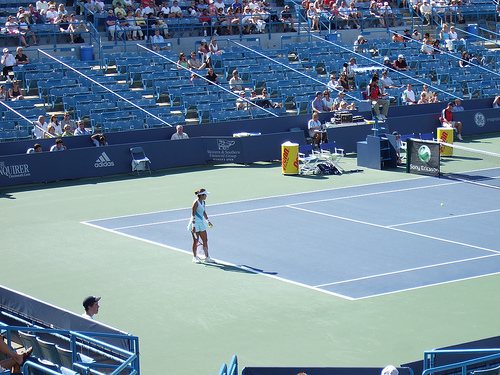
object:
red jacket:
[366, 83, 380, 99]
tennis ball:
[209, 225, 213, 229]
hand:
[208, 222, 212, 226]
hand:
[192, 227, 197, 234]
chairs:
[298, 147, 345, 176]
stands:
[0, 0, 500, 144]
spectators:
[392, 23, 465, 55]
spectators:
[32, 112, 92, 139]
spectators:
[177, 38, 226, 70]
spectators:
[299, 0, 460, 28]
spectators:
[0, 0, 80, 48]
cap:
[197, 189, 211, 195]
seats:
[11, 48, 289, 134]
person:
[229, 70, 245, 92]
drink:
[281, 141, 299, 175]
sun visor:
[205, 191, 211, 195]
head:
[195, 188, 208, 199]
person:
[171, 125, 189, 140]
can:
[281, 141, 299, 176]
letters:
[282, 148, 290, 170]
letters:
[293, 148, 299, 171]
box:
[187, 189, 214, 263]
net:
[406, 138, 500, 189]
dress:
[187, 221, 207, 232]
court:
[0, 0, 500, 375]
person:
[308, 113, 328, 147]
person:
[338, 72, 354, 92]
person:
[441, 102, 464, 140]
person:
[229, 70, 251, 93]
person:
[205, 69, 221, 85]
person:
[74, 120, 92, 136]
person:
[33, 115, 47, 139]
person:
[177, 52, 192, 70]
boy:
[82, 296, 102, 319]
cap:
[83, 295, 102, 306]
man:
[366, 76, 388, 120]